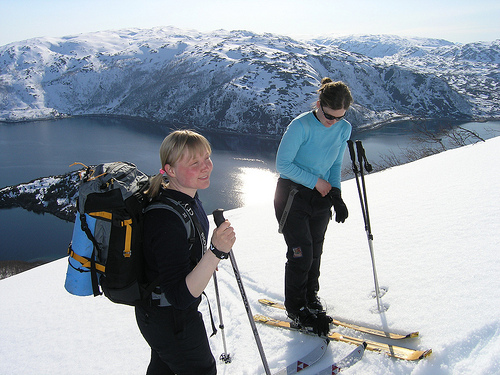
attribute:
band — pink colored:
[156, 166, 166, 176]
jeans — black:
[253, 167, 357, 327]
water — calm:
[4, 110, 159, 172]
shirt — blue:
[273, 110, 351, 190]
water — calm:
[94, 128, 141, 160]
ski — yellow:
[345, 332, 377, 356]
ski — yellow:
[336, 314, 368, 336]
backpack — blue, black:
[64, 161, 148, 303]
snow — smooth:
[397, 171, 498, 323]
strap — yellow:
[85, 207, 134, 258]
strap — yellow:
[66, 242, 106, 272]